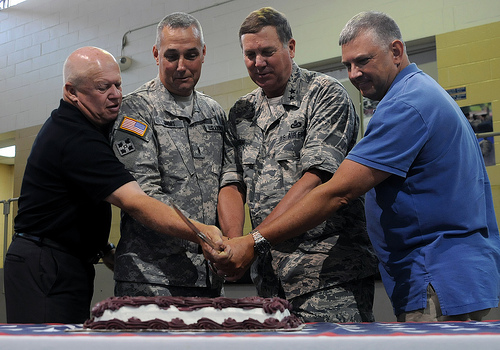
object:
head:
[63, 46, 123, 124]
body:
[1, 45, 224, 323]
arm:
[257, 104, 413, 245]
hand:
[216, 235, 256, 272]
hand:
[200, 225, 223, 262]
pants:
[3, 236, 96, 325]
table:
[0, 322, 500, 350]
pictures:
[459, 102, 495, 167]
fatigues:
[220, 57, 379, 323]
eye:
[358, 58, 371, 64]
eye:
[346, 64, 351, 69]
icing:
[86, 295, 291, 328]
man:
[2, 46, 226, 323]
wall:
[6, 2, 494, 309]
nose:
[350, 63, 363, 82]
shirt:
[344, 62, 499, 316]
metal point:
[168, 199, 219, 251]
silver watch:
[250, 230, 272, 256]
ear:
[391, 39, 404, 64]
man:
[109, 12, 226, 298]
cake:
[83, 296, 302, 329]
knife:
[173, 204, 223, 251]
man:
[218, 6, 380, 323]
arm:
[254, 104, 354, 232]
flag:
[120, 116, 148, 137]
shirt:
[13, 98, 136, 254]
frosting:
[90, 303, 288, 324]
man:
[212, 13, 500, 324]